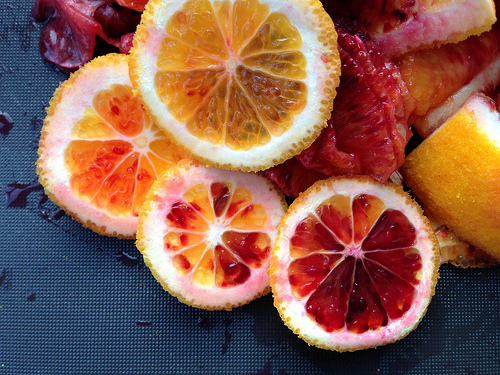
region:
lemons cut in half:
[20, 0, 498, 368]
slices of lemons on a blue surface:
[8, 8, 498, 348]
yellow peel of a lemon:
[401, 106, 498, 261]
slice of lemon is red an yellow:
[257, 181, 441, 363]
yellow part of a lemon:
[307, 163, 402, 217]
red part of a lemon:
[298, 221, 436, 351]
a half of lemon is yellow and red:
[118, 0, 343, 184]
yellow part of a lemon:
[128, 1, 266, 81]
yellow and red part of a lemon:
[190, 35, 338, 150]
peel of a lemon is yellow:
[132, 155, 286, 325]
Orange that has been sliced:
[282, 180, 446, 355]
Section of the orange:
[57, 135, 102, 175]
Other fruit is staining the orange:
[268, 205, 439, 328]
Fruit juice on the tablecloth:
[31, 297, 219, 340]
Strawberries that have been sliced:
[325, 38, 395, 178]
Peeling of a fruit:
[401, 97, 489, 207]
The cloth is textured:
[72, 290, 107, 350]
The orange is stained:
[157, 189, 264, 290]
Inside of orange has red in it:
[198, 53, 300, 128]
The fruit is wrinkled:
[338, 40, 396, 181]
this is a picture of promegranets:
[21, 11, 453, 274]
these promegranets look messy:
[35, 15, 460, 289]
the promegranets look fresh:
[66, 47, 445, 319]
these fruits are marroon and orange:
[71, 33, 454, 288]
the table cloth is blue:
[6, 181, 290, 368]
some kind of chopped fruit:
[31, 2, 141, 58]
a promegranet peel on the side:
[411, 109, 498, 237]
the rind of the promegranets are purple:
[42, 62, 289, 295]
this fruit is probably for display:
[57, 26, 477, 285]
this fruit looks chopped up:
[316, 19, 476, 178]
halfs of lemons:
[25, 0, 496, 365]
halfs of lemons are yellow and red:
[36, 0, 441, 342]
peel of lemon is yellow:
[123, 4, 157, 86]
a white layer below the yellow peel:
[127, 45, 157, 121]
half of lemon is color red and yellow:
[131, 159, 289, 314]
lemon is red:
[265, 180, 450, 357]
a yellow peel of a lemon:
[403, 100, 499, 261]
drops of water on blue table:
[1, 111, 36, 231]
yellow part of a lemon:
[148, 0, 261, 68]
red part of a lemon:
[213, 225, 264, 290]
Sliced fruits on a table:
[0, 0, 476, 371]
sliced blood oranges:
[5, 0, 475, 350]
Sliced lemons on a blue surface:
[5, 5, 485, 356]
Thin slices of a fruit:
[16, 0, 436, 370]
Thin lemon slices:
[15, 5, 435, 365]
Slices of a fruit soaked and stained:
[26, 64, 428, 361]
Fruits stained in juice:
[15, 15, 440, 346]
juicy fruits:
[0, 0, 455, 360]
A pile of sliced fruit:
[25, 1, 467, 346]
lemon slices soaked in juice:
[10, 0, 456, 370]